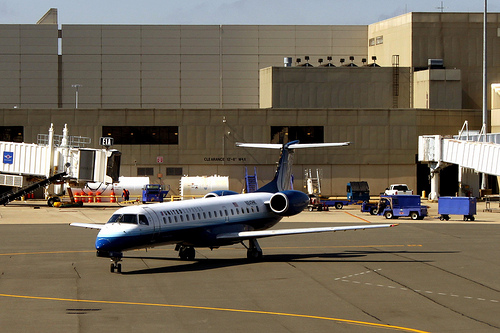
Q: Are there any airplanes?
A: Yes, there is an airplane.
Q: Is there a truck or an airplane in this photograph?
A: Yes, there is an airplane.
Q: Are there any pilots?
A: No, there are no pilots.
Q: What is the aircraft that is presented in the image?
A: The aircraft is an airplane.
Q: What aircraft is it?
A: The aircraft is an airplane.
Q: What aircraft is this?
A: That is an airplane.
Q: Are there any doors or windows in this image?
A: Yes, there is a window.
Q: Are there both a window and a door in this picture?
A: No, there is a window but no doors.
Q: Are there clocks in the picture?
A: No, there are no clocks.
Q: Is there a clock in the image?
A: No, there are no clocks.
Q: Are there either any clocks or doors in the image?
A: No, there are no clocks or doors.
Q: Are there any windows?
A: Yes, there is a window.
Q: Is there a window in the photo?
A: Yes, there is a window.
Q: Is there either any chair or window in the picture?
A: Yes, there is a window.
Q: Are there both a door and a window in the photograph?
A: No, there is a window but no doors.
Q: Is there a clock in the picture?
A: No, there are no clocks.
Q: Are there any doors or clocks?
A: No, there are no clocks or doors.